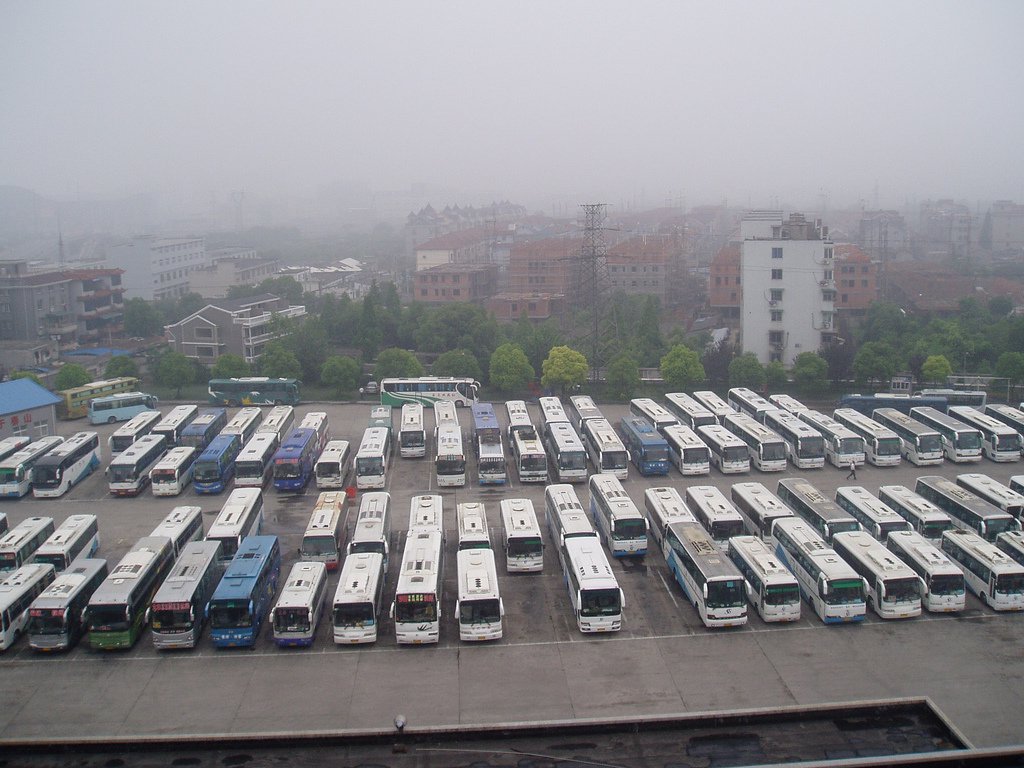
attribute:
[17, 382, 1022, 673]
buses — parked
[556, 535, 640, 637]
bus — white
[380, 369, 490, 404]
bus — wavy striped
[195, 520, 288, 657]
bus — blue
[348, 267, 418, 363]
bush — green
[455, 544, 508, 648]
bus — white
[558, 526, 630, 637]
bus — white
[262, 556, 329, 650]
bus — white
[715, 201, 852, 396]
building — white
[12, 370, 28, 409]
roof — blue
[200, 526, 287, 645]
bus — blue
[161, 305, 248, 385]
building — brown, white